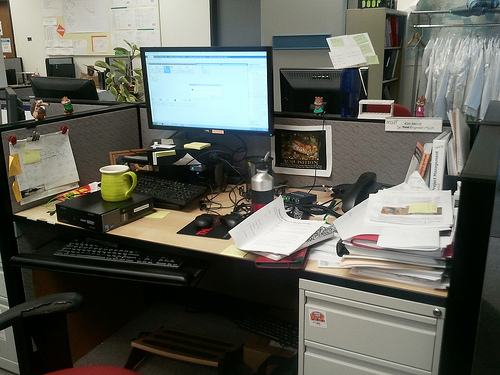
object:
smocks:
[419, 29, 500, 122]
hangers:
[406, 26, 426, 51]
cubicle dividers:
[0, 104, 140, 375]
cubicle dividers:
[438, 124, 499, 375]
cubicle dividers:
[138, 103, 480, 208]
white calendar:
[5, 129, 80, 206]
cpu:
[55, 189, 154, 233]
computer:
[138, 45, 273, 137]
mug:
[99, 165, 137, 202]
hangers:
[399, 9, 499, 123]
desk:
[13, 175, 451, 375]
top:
[426, 41, 436, 99]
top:
[440, 40, 445, 105]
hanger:
[404, 23, 425, 48]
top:
[462, 38, 485, 115]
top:
[484, 42, 493, 64]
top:
[488, 52, 496, 103]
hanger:
[412, 28, 428, 52]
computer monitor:
[139, 46, 274, 136]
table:
[14, 181, 451, 300]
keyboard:
[97, 169, 207, 206]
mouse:
[195, 213, 213, 228]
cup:
[99, 165, 137, 203]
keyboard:
[53, 236, 184, 269]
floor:
[160, 298, 243, 331]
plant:
[94, 38, 146, 104]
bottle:
[250, 161, 274, 216]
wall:
[32, 17, 146, 66]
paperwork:
[310, 108, 499, 290]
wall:
[6, 2, 346, 107]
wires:
[165, 111, 341, 222]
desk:
[13, 179, 448, 305]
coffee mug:
[99, 165, 137, 203]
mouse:
[195, 214, 242, 230]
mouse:
[219, 216, 243, 229]